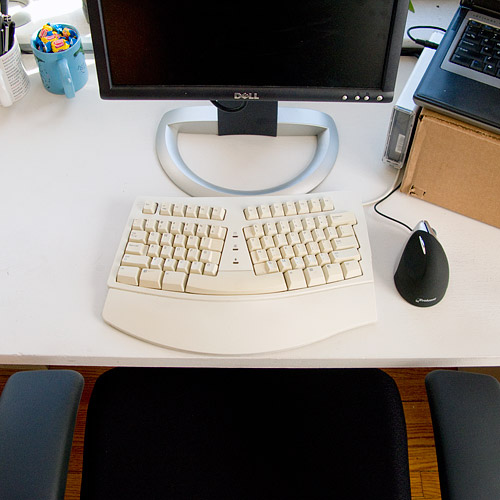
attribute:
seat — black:
[78, 366, 415, 499]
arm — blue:
[418, 368, 498, 499]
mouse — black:
[384, 222, 455, 314]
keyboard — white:
[97, 186, 386, 362]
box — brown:
[394, 99, 500, 227]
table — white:
[1, 1, 500, 371]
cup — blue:
[27, 21, 94, 101]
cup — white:
[1, 26, 35, 114]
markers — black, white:
[1, 11, 17, 57]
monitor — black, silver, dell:
[79, 0, 417, 202]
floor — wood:
[2, 367, 457, 497]